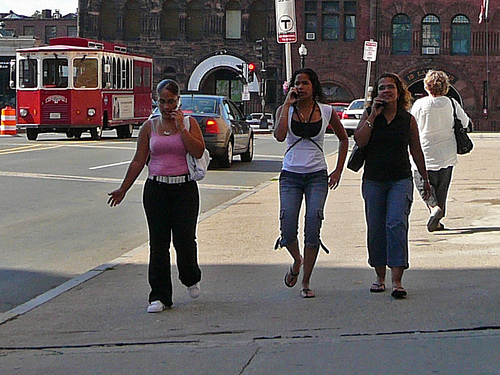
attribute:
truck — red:
[10, 37, 153, 142]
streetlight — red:
[247, 61, 254, 71]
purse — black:
[346, 143, 367, 173]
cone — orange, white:
[0, 106, 17, 140]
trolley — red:
[9, 35, 154, 141]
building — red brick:
[77, 1, 499, 135]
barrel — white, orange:
[1, 105, 15, 137]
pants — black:
[142, 173, 203, 306]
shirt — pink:
[147, 117, 188, 175]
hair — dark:
[291, 64, 328, 103]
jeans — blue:
[275, 169, 330, 255]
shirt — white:
[283, 100, 332, 174]